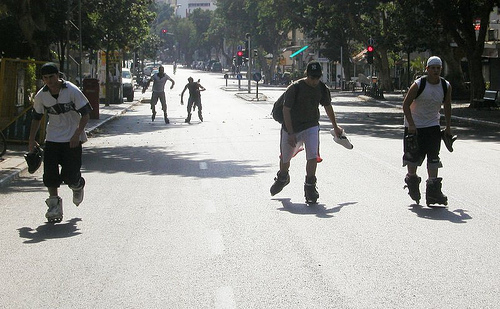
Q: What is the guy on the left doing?
A: Skating.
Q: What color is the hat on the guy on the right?
A: White.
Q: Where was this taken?
A: On a street.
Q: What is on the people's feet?
A: Roller blades.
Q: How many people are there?
A: 5.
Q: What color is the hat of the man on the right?
A: White.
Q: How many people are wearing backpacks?
A: 2.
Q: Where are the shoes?
A: In the men's hands.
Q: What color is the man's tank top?
A: White.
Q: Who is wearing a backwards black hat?
A: Man on the left.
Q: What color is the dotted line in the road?
A: White.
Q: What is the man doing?
A: Rollerblading.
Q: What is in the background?
A: Trees.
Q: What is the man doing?
A: Rollerblading.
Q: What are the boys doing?
A: Rollerblading.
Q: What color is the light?
A: Red.